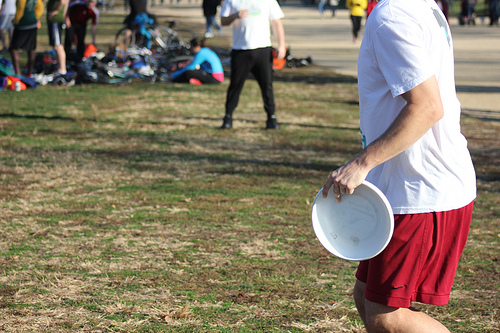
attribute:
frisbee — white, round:
[302, 180, 402, 275]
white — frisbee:
[42, 26, 78, 46]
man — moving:
[338, 16, 458, 118]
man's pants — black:
[233, 44, 279, 112]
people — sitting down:
[76, 11, 139, 63]